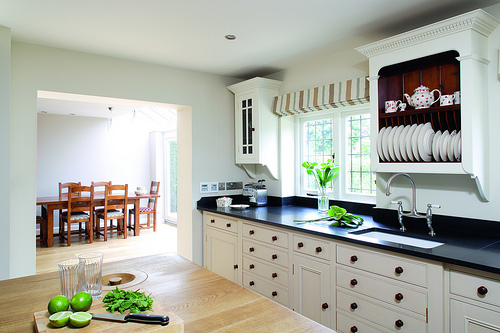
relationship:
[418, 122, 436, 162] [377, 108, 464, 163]
plate on rack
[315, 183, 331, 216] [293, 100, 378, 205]
vase by window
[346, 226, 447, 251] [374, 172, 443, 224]
sink has faucet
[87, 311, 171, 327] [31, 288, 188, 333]
knife on top of board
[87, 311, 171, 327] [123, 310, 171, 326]
knife has handle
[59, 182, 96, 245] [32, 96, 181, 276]
chair in dining room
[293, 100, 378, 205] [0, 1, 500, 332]
window in kitchen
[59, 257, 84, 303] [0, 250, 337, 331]
glass on top of counter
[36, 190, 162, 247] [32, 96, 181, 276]
table in dining room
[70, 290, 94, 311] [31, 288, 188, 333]
lime on top of board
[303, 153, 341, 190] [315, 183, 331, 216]
flower in vase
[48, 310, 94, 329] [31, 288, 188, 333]
lime on top of board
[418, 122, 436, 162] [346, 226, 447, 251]
plate over sink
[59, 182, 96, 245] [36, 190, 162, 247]
chair beside table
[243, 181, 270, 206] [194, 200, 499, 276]
toaster on top of counter top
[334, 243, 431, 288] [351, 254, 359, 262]
drawer has knob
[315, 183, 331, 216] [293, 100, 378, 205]
vase in front of window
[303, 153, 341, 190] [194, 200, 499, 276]
flower on top of counter top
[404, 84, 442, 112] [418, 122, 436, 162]
teapot over plate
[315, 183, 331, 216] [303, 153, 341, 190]
vase has flower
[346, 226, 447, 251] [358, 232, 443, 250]
sink has basin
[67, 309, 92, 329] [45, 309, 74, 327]
lime half next to lime half